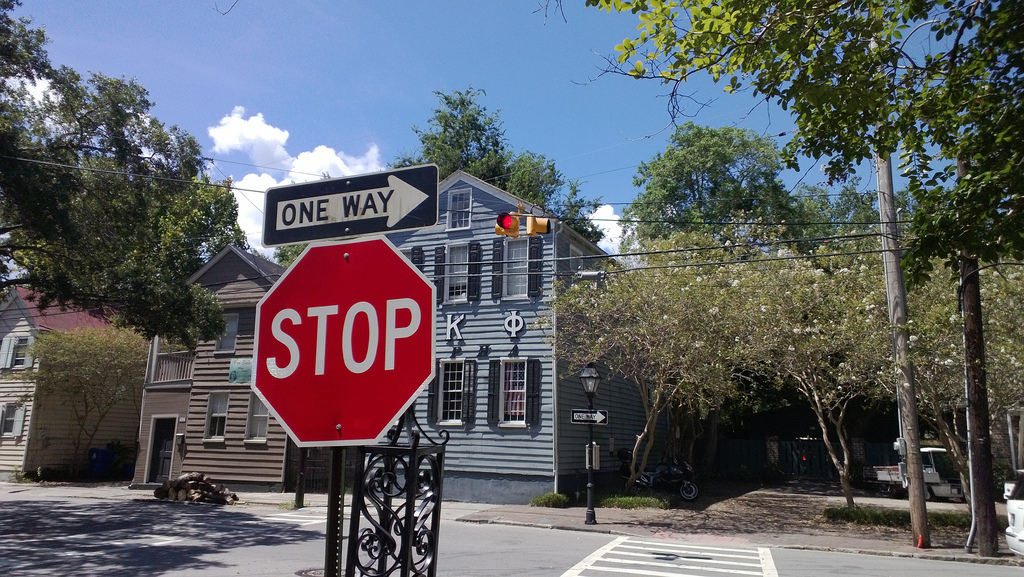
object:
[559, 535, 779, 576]
lines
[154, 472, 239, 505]
fire wood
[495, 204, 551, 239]
lights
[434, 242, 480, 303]
shutters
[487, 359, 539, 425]
shutters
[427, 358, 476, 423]
shutters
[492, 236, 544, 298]
shutters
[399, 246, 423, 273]
shutters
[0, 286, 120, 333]
roof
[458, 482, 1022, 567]
sidewalk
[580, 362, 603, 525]
light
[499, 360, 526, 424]
window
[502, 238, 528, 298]
window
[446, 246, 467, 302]
window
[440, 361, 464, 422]
window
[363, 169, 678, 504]
building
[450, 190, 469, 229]
window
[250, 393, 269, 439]
window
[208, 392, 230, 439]
window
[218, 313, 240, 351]
window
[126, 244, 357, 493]
building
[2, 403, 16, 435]
window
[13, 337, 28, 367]
window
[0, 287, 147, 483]
building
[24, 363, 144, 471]
wall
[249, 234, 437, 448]
sign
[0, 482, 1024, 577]
ground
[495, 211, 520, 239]
traffic light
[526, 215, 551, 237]
traffic light